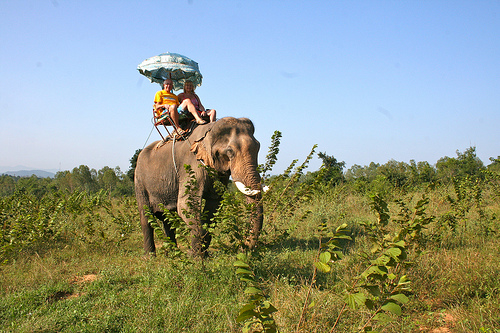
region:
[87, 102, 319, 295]
elephant walking in a field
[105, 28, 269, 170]
couple on top of the elephant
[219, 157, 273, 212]
white elephant tusks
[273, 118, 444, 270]
green plants in a field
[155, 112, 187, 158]
chair saddle for elephant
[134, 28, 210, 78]
blue umbrella over couple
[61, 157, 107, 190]
green trees in field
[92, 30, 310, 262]
elephant with couple on its back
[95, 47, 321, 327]
couple riding on the back of elephant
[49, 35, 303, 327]
elephant in a field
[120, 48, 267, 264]
two people riding an elephant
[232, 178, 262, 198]
large white elephant tusk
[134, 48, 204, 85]
blue umbrella with embellishments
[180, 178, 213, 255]
front leg of an elephant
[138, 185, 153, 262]
hind leg of an elephant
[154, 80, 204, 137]
man wearing yellow shirt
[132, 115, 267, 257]
large grey elephant with white tusks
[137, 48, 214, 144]
two people under an umbrella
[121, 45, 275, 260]
people with an umbrella on an elephant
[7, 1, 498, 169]
clear sky with no clouds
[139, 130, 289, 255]
the elephant is greyish brown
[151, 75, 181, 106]
this person is wearing a yellow shirt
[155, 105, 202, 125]
the shorts are a blue color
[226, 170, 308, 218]
the elephant has white tusk's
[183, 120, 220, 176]
the elephant has a big ear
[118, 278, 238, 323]
the grass is a green color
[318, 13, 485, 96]
the sky is a blue color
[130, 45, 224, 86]
the unbrella is a blue color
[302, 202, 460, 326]
the weeds are green with a brown stem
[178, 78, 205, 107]
this person is wearing a red and white shirt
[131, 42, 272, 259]
elephant with two people riding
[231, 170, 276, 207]
tusks on large elephant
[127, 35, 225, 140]
umbrella shading people from sun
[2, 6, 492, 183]
clear cloudless sky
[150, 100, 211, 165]
two person elephant saddle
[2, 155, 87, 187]
mountains in distant background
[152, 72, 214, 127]
two people smiling for camera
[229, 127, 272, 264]
elephant trunk hanging towards ground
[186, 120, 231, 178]
elephant ear flat against body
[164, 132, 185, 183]
strap holding saddle on elephant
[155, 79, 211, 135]
couple sitting on an elephant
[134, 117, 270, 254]
a big grey elephant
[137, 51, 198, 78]
a big blue umbrella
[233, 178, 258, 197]
an elephant's right tusk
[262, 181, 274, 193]
an elephant's left tusk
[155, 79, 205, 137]
man in a yellow shirt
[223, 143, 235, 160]
an elephant's right eye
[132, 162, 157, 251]
an elephant's right rear leg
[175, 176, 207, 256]
an elephant's right front leg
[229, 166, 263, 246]
an elephant's long trunk